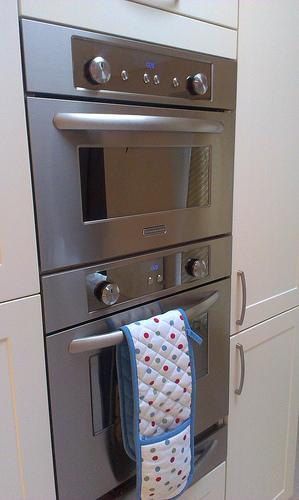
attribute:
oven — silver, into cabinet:
[60, 34, 270, 244]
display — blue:
[120, 63, 171, 88]